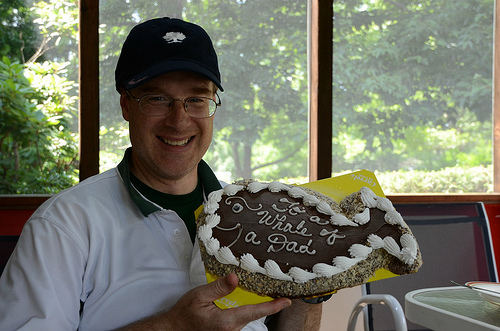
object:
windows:
[0, 0, 499, 206]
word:
[308, 214, 330, 225]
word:
[317, 227, 345, 246]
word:
[256, 210, 314, 237]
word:
[263, 231, 315, 256]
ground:
[342, 45, 435, 192]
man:
[0, 15, 325, 331]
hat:
[115, 17, 226, 90]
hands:
[170, 273, 291, 330]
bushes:
[0, 0, 76, 192]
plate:
[406, 285, 500, 330]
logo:
[163, 31, 186, 43]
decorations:
[220, 191, 344, 261]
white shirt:
[0, 144, 266, 330]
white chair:
[346, 294, 407, 331]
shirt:
[0, 144, 270, 329]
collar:
[118, 147, 224, 219]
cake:
[197, 178, 420, 296]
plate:
[192, 170, 414, 310]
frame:
[317, 0, 330, 178]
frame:
[81, 0, 99, 178]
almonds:
[203, 251, 422, 296]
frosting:
[200, 181, 419, 280]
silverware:
[451, 277, 500, 296]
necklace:
[130, 173, 204, 195]